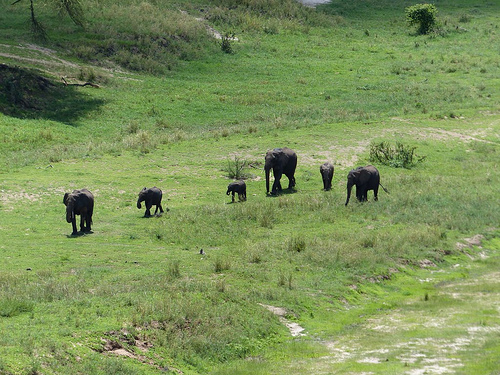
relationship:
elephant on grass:
[61, 190, 96, 236] [1, 1, 499, 373]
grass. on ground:
[0, 233, 498, 374] [25, 238, 483, 349]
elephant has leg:
[343, 167, 390, 208] [369, 188, 379, 200]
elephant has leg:
[318, 163, 332, 190] [269, 174, 283, 196]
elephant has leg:
[262, 150, 299, 197] [269, 174, 283, 196]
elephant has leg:
[224, 180, 249, 203] [151, 205, 159, 216]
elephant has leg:
[136, 187, 165, 218] [69, 218, 77, 233]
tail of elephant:
[377, 179, 392, 194] [341, 161, 393, 206]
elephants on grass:
[51, 146, 395, 237] [1, 1, 499, 373]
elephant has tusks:
[58, 187, 96, 237] [67, 207, 77, 221]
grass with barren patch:
[1, 1, 499, 373] [258, 298, 303, 338]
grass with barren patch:
[1, 1, 499, 373] [321, 331, 494, 372]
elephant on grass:
[217, 175, 252, 211] [1, 1, 499, 373]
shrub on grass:
[369, 140, 426, 170] [1, 1, 499, 373]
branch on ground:
[66, 1, 227, 92] [1, 0, 498, 372]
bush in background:
[403, 0, 450, 38] [25, 1, 496, 107]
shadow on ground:
[12, 78, 71, 154] [2, 52, 495, 375]